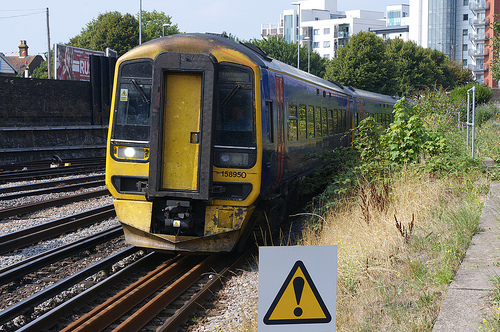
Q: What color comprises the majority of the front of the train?
A: Yellow.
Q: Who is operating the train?
A: Train Engineer.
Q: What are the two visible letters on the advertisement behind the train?
A: RU.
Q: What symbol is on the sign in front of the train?
A: Exclamation point.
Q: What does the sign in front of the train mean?
A: Caution.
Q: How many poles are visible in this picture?
A: Eight.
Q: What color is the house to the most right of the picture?
A: Red.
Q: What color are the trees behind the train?
A: Green.